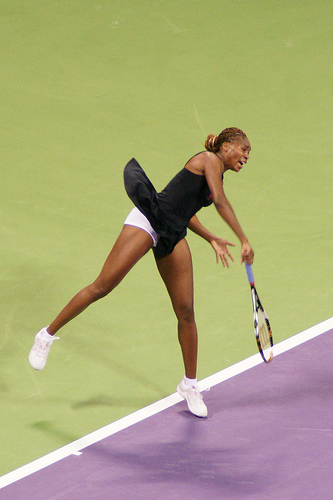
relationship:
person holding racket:
[28, 128, 251, 418] [241, 249, 275, 363]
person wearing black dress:
[28, 128, 251, 418] [123, 150, 224, 260]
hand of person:
[206, 234, 238, 273] [162, 102, 273, 245]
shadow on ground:
[30, 392, 296, 497] [0, 1, 322, 498]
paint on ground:
[281, 316, 333, 352] [0, 1, 322, 498]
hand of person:
[240, 235, 254, 265] [165, 121, 270, 264]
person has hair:
[28, 128, 251, 418] [199, 122, 252, 155]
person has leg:
[28, 128, 251, 418] [22, 202, 153, 371]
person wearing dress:
[28, 128, 251, 418] [110, 133, 234, 265]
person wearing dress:
[28, 128, 251, 418] [123, 150, 220, 259]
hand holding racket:
[232, 233, 264, 270] [240, 249, 274, 363]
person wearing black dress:
[28, 128, 251, 418] [119, 155, 220, 259]